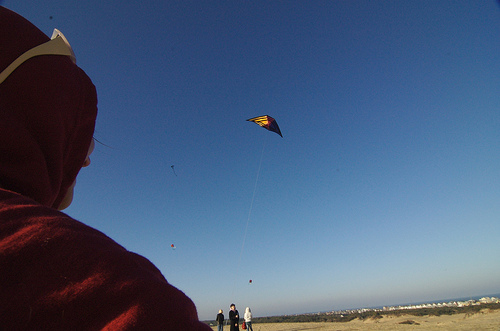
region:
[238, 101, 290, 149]
kite in air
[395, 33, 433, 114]
white clouds in blue sky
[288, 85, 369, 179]
white clouds in blue sky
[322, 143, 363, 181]
white clouds in blue sky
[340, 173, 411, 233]
white clouds in blue sky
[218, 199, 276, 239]
white clouds in blue sky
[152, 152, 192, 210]
white clouds in blue sky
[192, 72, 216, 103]
white clouds in blue sky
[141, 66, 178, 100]
white clouds in blue sky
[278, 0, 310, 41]
white clouds in blue sky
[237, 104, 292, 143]
Blue and yellow kite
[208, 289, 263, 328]
Three people flying a kite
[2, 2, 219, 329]
Someone looking at the people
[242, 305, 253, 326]
Person in white jacket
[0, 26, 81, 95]
White sunglasses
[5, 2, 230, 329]
Person in red hoodie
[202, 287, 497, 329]
Trees in the distance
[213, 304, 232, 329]
Person in black shirt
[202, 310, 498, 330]
Sand on the beach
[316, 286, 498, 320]
Buildings in the distance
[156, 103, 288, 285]
several kites flying in blue sky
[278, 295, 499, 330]
several white structures at horizon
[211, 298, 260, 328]
three people standing together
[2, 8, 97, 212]
back of person wearing white sunglasses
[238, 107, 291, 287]
one bright kite flying high in sky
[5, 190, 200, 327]
red shoulder of sweatshirt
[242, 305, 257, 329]
person wearing white hooded coat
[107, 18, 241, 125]
section of vivid blue sky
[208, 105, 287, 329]
three people looking at a kite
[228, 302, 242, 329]
one person wearing a dark coat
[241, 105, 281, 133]
kite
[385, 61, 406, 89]
white clouds in blue sky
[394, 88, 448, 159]
white clouds in blue sky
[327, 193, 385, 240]
white clouds in blue sky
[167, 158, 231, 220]
white clouds in blue sky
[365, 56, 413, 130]
white clouds in blue sky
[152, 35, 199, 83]
white clouds in blue sky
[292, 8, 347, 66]
white clouds in blue sky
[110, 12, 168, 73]
white clouds in blue sky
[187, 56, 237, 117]
white clouds in blue sky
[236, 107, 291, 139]
kite in the sky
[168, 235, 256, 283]
kites in the sky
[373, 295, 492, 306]
buildings in the back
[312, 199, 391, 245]
the sky is clear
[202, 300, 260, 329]
people in the background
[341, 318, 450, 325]
yellow grass on ground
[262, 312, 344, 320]
trees in the back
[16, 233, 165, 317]
red shirt on man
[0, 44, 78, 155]
back of the head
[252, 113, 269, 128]
yellow part of kite